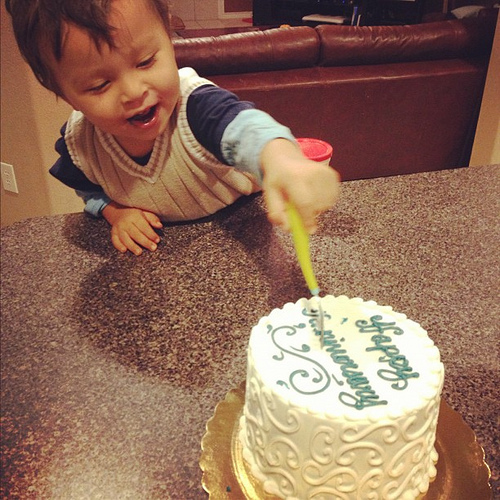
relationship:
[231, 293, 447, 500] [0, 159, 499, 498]
cake on table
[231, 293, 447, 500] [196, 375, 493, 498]
cake on cardboard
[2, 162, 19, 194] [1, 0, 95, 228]
outlet on wall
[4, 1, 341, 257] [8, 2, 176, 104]
boy has hair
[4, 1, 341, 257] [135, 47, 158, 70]
boy has eye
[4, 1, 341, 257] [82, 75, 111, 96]
boy has eye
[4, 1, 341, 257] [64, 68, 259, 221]
boy wears vest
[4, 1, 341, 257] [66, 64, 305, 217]
boy wears shirt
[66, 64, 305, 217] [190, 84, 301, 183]
shirt has sleeve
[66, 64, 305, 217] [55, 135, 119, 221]
shirt has sleeve